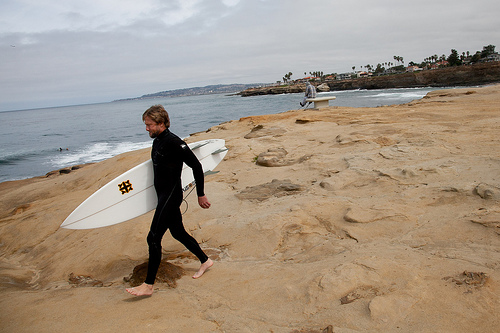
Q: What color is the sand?
A: Tan.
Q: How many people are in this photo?
A: 1.